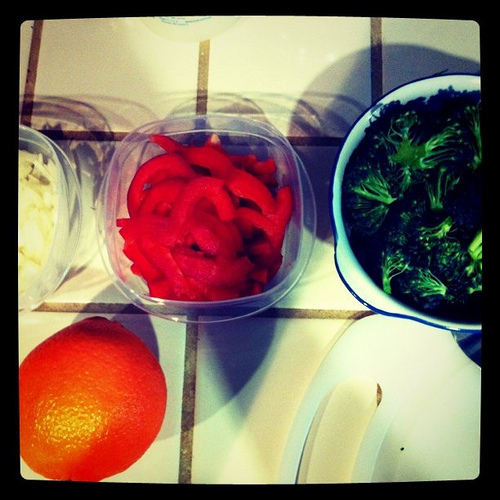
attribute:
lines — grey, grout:
[1, 41, 351, 489]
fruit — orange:
[26, 317, 162, 469]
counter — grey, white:
[20, 158, 467, 482]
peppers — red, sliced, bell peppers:
[119, 133, 291, 295]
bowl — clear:
[127, 135, 294, 295]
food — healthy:
[126, 137, 277, 290]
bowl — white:
[319, 59, 494, 348]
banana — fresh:
[274, 366, 384, 494]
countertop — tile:
[25, 22, 477, 479]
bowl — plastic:
[95, 115, 317, 324]